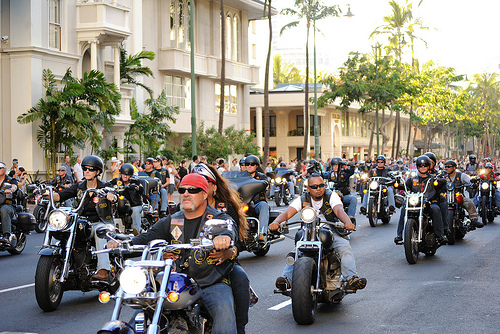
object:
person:
[105, 172, 239, 334]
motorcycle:
[97, 222, 260, 334]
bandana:
[178, 172, 207, 193]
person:
[32, 155, 120, 281]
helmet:
[81, 155, 103, 174]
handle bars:
[90, 239, 233, 256]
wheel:
[32, 249, 66, 312]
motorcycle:
[32, 185, 129, 311]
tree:
[308, 51, 427, 163]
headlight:
[119, 266, 148, 294]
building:
[249, 90, 453, 163]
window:
[252, 115, 277, 138]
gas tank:
[183, 308, 209, 333]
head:
[177, 173, 209, 211]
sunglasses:
[178, 187, 204, 194]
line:
[266, 297, 293, 311]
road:
[363, 271, 498, 333]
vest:
[161, 213, 232, 282]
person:
[269, 177, 368, 292]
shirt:
[287, 189, 346, 228]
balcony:
[288, 127, 321, 139]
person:
[191, 161, 252, 333]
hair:
[207, 166, 249, 243]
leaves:
[310, 51, 425, 116]